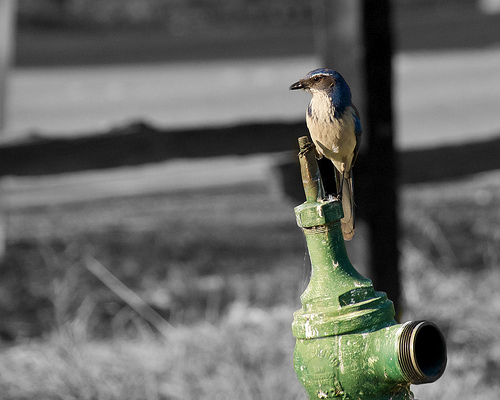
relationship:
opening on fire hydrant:
[391, 314, 451, 390] [290, 139, 447, 399]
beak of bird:
[285, 78, 310, 92] [279, 60, 374, 250]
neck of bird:
[308, 90, 348, 111] [287, 67, 365, 244]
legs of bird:
[302, 144, 346, 214] [287, 67, 366, 201]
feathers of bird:
[304, 66, 364, 241] [287, 67, 365, 244]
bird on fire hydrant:
[287, 67, 365, 244] [290, 135, 446, 398]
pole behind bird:
[312, 5, 402, 334] [260, 55, 387, 247]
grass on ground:
[46, 324, 128, 383] [115, 352, 250, 397]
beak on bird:
[289, 79, 306, 89] [254, 50, 383, 214]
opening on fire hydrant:
[411, 321, 448, 381] [290, 135, 446, 398]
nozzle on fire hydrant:
[288, 131, 328, 218] [290, 135, 446, 398]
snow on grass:
[2, 235, 458, 398] [10, 244, 290, 396]